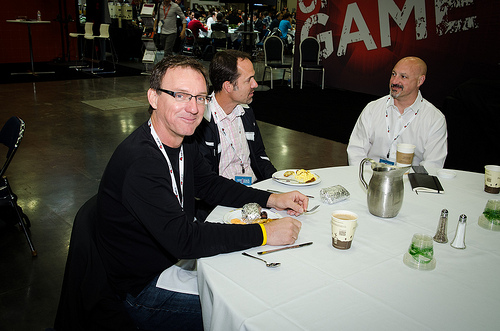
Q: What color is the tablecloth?
A: White.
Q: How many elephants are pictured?
A: Zero.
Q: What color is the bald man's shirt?
A: White.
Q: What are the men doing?
A: Sitting at a table.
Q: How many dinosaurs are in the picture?
A: Zero.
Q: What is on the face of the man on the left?
A: Glasses.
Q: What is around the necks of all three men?
A: Lanyard.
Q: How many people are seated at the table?
A: Three.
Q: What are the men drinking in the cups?
A: Coffee.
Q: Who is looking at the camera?
A: The man in glasses.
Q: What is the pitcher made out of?
A: Metal.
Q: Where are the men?
A: Seated at a table.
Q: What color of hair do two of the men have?
A: Brown.